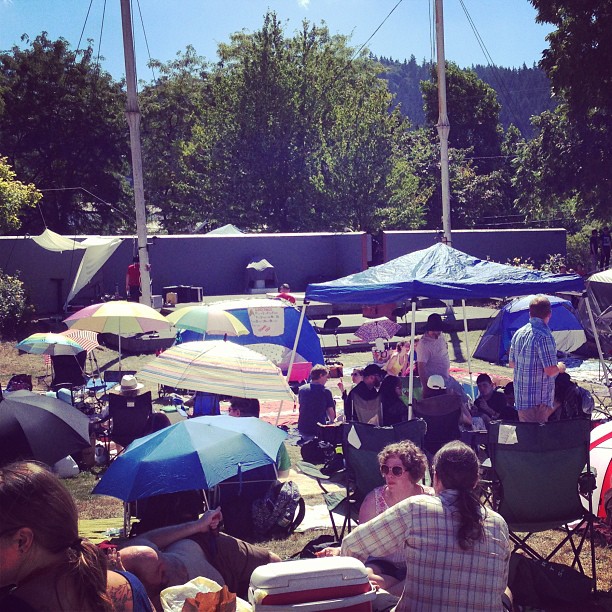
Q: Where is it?
A: This is at the park.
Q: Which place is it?
A: It is a park.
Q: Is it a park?
A: Yes, it is a park.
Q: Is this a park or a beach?
A: It is a park.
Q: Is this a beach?
A: No, it is a park.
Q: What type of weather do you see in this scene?
A: It is clear.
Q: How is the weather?
A: It is clear.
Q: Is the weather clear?
A: Yes, it is clear.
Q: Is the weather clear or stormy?
A: It is clear.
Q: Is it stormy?
A: No, it is clear.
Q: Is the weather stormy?
A: No, it is clear.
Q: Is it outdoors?
A: Yes, it is outdoors.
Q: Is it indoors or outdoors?
A: It is outdoors.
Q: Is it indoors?
A: No, it is outdoors.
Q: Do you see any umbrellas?
A: Yes, there is an umbrella.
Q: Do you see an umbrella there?
A: Yes, there is an umbrella.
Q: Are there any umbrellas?
A: Yes, there is an umbrella.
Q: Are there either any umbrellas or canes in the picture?
A: Yes, there is an umbrella.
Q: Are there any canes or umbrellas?
A: Yes, there is an umbrella.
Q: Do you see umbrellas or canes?
A: Yes, there is an umbrella.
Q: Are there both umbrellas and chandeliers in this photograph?
A: No, there is an umbrella but no chandeliers.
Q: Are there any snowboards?
A: No, there are no snowboards.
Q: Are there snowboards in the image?
A: No, there are no snowboards.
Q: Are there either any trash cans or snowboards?
A: No, there are no snowboards or trash cans.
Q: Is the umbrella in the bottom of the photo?
A: Yes, the umbrella is in the bottom of the image.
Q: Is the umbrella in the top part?
A: No, the umbrella is in the bottom of the image.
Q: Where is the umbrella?
A: The umbrella is in the park.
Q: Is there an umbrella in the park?
A: Yes, there is an umbrella in the park.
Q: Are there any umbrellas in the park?
A: Yes, there is an umbrella in the park.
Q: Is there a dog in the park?
A: No, there is an umbrella in the park.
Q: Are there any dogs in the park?
A: No, there is an umbrella in the park.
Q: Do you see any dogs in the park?
A: No, there is an umbrella in the park.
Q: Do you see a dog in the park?
A: No, there is an umbrella in the park.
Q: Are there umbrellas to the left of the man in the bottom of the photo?
A: Yes, there is an umbrella to the left of the man.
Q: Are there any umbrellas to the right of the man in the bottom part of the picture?
A: No, the umbrella is to the left of the man.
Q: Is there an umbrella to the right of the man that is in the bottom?
A: No, the umbrella is to the left of the man.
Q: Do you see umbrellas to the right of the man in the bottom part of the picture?
A: No, the umbrella is to the left of the man.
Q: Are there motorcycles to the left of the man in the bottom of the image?
A: No, there is an umbrella to the left of the man.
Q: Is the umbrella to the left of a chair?
A: No, the umbrella is to the left of the man.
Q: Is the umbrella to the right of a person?
A: No, the umbrella is to the left of a person.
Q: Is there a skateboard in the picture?
A: No, there are no skateboards.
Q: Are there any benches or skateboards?
A: No, there are no skateboards or benches.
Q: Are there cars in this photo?
A: No, there are no cars.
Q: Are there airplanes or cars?
A: No, there are no cars or airplanes.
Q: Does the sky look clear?
A: Yes, the sky is clear.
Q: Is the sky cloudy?
A: No, the sky is clear.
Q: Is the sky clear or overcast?
A: The sky is clear.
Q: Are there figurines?
A: No, there are no figurines.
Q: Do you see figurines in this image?
A: No, there are no figurines.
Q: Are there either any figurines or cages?
A: No, there are no figurines or cages.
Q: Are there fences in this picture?
A: Yes, there is a fence.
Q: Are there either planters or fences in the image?
A: Yes, there is a fence.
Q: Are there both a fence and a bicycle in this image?
A: No, there is a fence but no bicycles.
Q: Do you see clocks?
A: No, there are no clocks.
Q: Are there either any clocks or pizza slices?
A: No, there are no clocks or pizza slices.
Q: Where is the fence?
A: The fence is in the park.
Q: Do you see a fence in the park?
A: Yes, there is a fence in the park.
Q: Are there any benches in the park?
A: No, there is a fence in the park.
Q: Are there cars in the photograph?
A: No, there are no cars.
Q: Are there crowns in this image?
A: No, there are no crowns.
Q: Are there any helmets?
A: No, there are no helmets.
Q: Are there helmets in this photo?
A: No, there are no helmets.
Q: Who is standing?
A: The man is standing.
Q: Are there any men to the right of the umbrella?
A: Yes, there is a man to the right of the umbrella.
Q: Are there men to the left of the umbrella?
A: No, the man is to the right of the umbrella.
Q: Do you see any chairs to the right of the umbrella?
A: No, there is a man to the right of the umbrella.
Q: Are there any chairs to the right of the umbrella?
A: No, there is a man to the right of the umbrella.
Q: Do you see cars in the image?
A: No, there are no cars.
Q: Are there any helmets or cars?
A: No, there are no cars or helmets.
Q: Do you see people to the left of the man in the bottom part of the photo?
A: Yes, there is a person to the left of the man.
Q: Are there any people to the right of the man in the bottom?
A: No, the person is to the left of the man.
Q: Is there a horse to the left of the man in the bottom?
A: No, there is a person to the left of the man.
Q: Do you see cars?
A: No, there are no cars.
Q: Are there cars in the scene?
A: No, there are no cars.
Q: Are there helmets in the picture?
A: No, there are no helmets.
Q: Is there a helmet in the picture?
A: No, there are no helmets.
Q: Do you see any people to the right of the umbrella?
A: Yes, there is a person to the right of the umbrella.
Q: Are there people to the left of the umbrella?
A: No, the person is to the right of the umbrella.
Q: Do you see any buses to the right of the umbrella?
A: No, there is a person to the right of the umbrella.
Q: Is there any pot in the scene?
A: No, there are no pots.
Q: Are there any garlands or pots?
A: No, there are no pots or garlands.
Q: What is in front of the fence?
A: The canopy is in front of the fence.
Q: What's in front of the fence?
A: The canopy is in front of the fence.